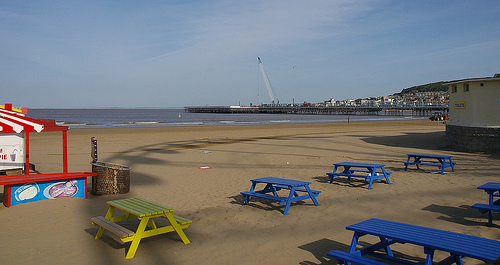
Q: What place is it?
A: It is a beach.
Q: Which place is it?
A: It is a beach.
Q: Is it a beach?
A: Yes, it is a beach.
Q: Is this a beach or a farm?
A: It is a beach.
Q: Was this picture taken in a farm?
A: No, the picture was taken in a beach.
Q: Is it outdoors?
A: Yes, it is outdoors.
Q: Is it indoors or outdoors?
A: It is outdoors.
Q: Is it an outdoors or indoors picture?
A: It is outdoors.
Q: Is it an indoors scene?
A: No, it is outdoors.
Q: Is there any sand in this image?
A: Yes, there is sand.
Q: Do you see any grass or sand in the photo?
A: Yes, there is sand.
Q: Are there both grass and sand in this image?
A: No, there is sand but no grass.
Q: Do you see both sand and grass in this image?
A: No, there is sand but no grass.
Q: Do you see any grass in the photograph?
A: No, there is no grass.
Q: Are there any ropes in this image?
A: No, there are no ropes.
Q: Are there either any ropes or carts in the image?
A: No, there are no ropes or carts.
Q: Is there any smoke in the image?
A: Yes, there is smoke.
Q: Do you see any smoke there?
A: Yes, there is smoke.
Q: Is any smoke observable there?
A: Yes, there is smoke.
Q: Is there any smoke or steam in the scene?
A: Yes, there is smoke.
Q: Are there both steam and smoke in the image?
A: No, there is smoke but no steam.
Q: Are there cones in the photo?
A: No, there are no cones.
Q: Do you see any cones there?
A: No, there are no cones.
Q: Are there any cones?
A: No, there are no cones.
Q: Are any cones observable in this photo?
A: No, there are no cones.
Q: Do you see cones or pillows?
A: No, there are no cones or pillows.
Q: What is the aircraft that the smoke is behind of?
A: The aircraft is a jet.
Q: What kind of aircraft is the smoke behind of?
A: The smoke is behind the jet.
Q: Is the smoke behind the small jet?
A: Yes, the smoke is behind the jet.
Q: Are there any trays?
A: No, there are no trays.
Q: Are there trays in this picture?
A: No, there are no trays.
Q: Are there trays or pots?
A: No, there are no trays or pots.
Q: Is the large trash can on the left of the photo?
A: Yes, the garbage can is on the left of the image.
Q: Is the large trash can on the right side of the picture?
A: No, the trash can is on the left of the image.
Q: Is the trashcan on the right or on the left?
A: The trashcan is on the left of the image.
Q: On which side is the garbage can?
A: The garbage can is on the left of the image.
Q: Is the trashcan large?
A: Yes, the trashcan is large.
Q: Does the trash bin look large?
A: Yes, the trash bin is large.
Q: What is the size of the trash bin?
A: The trash bin is large.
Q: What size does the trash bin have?
A: The trash bin has large size.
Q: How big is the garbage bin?
A: The garbage bin is large.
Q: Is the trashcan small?
A: No, the trashcan is large.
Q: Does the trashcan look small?
A: No, the trashcan is large.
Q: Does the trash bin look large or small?
A: The trash bin is large.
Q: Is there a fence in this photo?
A: No, there are no fences.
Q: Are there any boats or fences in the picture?
A: No, there are no fences or boats.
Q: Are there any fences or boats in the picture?
A: No, there are no fences or boats.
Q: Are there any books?
A: No, there are no books.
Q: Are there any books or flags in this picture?
A: No, there are no books or flags.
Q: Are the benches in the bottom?
A: Yes, the benches are in the bottom of the image.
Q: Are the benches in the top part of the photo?
A: No, the benches are in the bottom of the image.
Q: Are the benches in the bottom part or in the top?
A: The benches are in the bottom of the image.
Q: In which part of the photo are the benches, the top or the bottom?
A: The benches are in the bottom of the image.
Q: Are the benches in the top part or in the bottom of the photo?
A: The benches are in the bottom of the image.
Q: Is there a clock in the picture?
A: No, there are no clocks.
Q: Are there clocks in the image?
A: No, there are no clocks.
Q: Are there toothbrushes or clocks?
A: No, there are no clocks or toothbrushes.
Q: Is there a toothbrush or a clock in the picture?
A: No, there are no clocks or toothbrushes.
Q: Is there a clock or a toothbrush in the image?
A: No, there are no clocks or toothbrushes.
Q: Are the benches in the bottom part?
A: Yes, the benches are in the bottom of the image.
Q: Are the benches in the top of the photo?
A: No, the benches are in the bottom of the image.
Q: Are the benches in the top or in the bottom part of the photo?
A: The benches are in the bottom of the image.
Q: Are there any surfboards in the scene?
A: No, there are no surfboards.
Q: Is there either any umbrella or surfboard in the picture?
A: No, there are no surfboards or umbrellas.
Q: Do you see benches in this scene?
A: Yes, there is a bench.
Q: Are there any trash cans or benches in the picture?
A: Yes, there is a bench.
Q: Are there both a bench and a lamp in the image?
A: No, there is a bench but no lamps.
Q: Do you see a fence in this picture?
A: No, there are no fences.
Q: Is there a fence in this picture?
A: No, there are no fences.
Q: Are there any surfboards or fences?
A: No, there are no fences or surfboards.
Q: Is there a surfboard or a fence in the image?
A: No, there are no fences or surfboards.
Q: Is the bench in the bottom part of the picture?
A: Yes, the bench is in the bottom of the image.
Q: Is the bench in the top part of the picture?
A: No, the bench is in the bottom of the image.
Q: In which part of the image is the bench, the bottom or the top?
A: The bench is in the bottom of the image.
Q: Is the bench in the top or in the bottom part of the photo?
A: The bench is in the bottom of the image.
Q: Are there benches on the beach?
A: Yes, there is a bench on the beach.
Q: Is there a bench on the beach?
A: Yes, there is a bench on the beach.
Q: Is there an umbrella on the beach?
A: No, there is a bench on the beach.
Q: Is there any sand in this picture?
A: Yes, there is sand.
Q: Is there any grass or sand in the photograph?
A: Yes, there is sand.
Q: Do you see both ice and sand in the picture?
A: No, there is sand but no ice.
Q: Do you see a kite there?
A: No, there are no kites.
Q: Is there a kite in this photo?
A: No, there are no kites.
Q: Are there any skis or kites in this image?
A: No, there are no kites or skis.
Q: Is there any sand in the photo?
A: Yes, there is sand.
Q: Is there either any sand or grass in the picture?
A: Yes, there is sand.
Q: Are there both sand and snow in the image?
A: No, there is sand but no snow.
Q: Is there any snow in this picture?
A: No, there is no snow.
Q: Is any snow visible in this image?
A: No, there is no snow.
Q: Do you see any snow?
A: No, there is no snow.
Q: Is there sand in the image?
A: Yes, there is sand.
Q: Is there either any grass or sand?
A: Yes, there is sand.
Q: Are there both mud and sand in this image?
A: No, there is sand but no mud.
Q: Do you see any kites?
A: No, there are no kites.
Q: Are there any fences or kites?
A: No, there are no kites or fences.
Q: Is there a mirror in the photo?
A: No, there are no mirrors.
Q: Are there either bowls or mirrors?
A: No, there are no mirrors or bowls.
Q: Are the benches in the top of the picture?
A: No, the benches are in the bottom of the image.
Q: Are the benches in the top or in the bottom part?
A: The benches are in the bottom of the image.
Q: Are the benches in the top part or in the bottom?
A: The benches are in the bottom of the image.